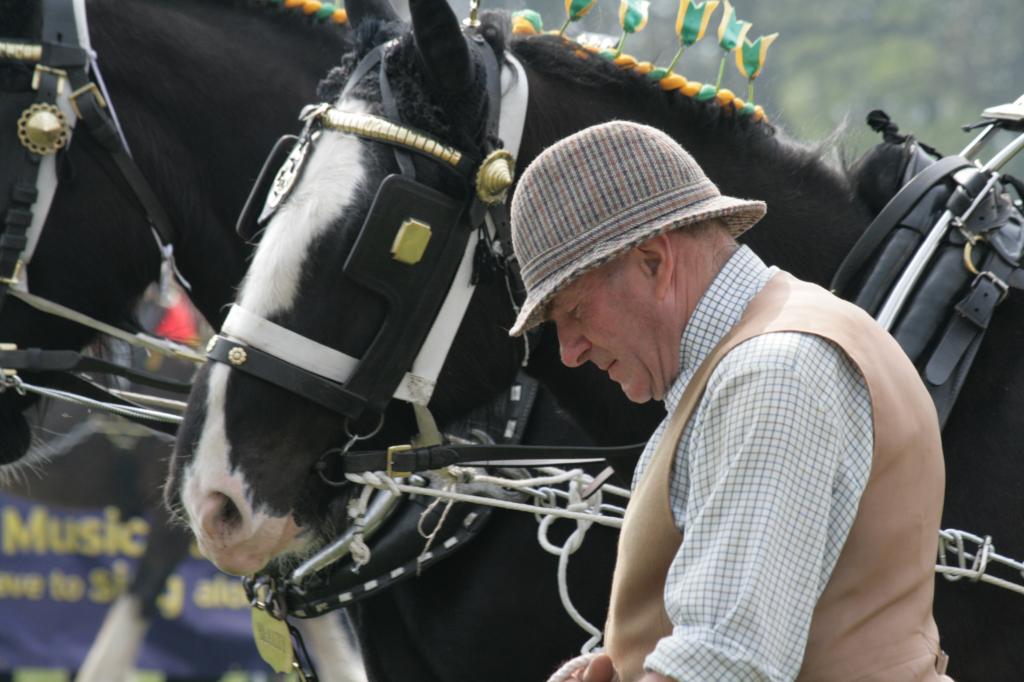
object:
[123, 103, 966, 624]
outdoors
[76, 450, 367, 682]
people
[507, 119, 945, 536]
person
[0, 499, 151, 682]
sign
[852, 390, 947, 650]
vest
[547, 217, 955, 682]
man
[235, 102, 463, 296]
horse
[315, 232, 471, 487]
covers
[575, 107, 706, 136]
mane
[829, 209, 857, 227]
green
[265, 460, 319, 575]
mouth bit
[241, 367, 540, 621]
bridle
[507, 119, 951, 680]
man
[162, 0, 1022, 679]
horse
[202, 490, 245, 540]
muzzle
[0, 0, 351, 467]
horse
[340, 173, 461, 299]
blinders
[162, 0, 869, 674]
horse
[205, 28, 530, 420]
harness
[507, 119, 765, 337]
hat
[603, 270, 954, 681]
vest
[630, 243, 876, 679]
shirt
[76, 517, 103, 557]
letter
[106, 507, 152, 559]
letter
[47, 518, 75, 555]
letter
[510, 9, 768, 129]
ribon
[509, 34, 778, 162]
mane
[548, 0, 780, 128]
flags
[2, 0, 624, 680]
horse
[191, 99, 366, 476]
mark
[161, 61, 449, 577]
face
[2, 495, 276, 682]
banner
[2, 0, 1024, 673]
horses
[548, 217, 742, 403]
head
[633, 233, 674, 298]
ear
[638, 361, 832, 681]
arm